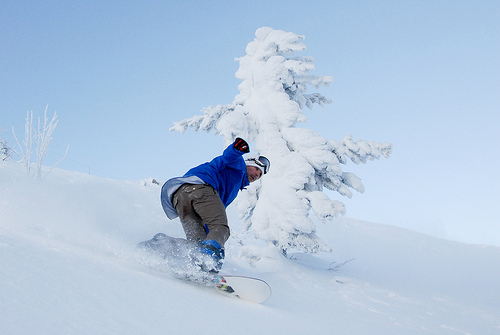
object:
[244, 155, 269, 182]
`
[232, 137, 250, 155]
glove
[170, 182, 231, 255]
pants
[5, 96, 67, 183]
tree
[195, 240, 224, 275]
boot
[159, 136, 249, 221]
blue jacket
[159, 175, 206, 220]
shirttail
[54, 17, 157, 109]
sky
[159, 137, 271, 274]
man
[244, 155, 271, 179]
helmet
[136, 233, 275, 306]
board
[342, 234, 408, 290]
white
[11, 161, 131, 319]
slope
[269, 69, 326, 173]
snow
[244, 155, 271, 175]
glasses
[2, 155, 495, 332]
snow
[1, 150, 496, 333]
ground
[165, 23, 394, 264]
tree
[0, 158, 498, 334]
ocean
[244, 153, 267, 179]
hat